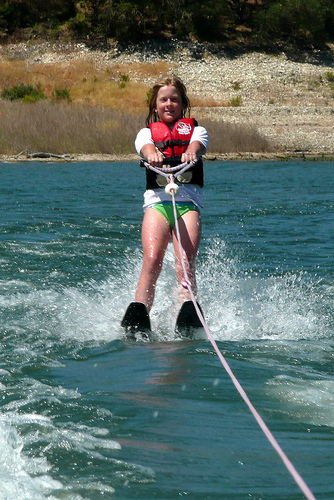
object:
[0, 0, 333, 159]
hillside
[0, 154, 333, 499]
lake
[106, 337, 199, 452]
shadow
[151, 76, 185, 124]
head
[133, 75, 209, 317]
girl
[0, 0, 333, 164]
ground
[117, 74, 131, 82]
grass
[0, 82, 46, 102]
bushes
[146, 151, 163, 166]
hand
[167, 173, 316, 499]
rope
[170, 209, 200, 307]
leg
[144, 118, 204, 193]
life jacket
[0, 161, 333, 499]
blue water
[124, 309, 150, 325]
foot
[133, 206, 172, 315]
leg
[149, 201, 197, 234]
bikini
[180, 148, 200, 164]
hand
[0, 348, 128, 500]
waves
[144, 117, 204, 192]
vest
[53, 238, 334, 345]
waves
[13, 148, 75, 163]
wood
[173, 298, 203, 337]
skis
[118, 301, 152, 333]
skis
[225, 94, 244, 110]
grass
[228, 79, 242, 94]
grass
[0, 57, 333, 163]
shore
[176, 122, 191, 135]
symbol